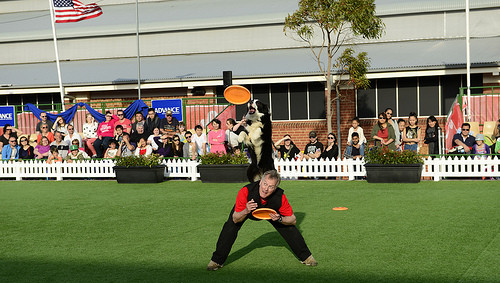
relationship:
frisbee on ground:
[327, 201, 356, 214] [6, 178, 499, 278]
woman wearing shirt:
[31, 136, 54, 159] [37, 140, 49, 153]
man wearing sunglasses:
[450, 123, 476, 159] [463, 125, 471, 133]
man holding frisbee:
[208, 167, 317, 267] [244, 202, 281, 223]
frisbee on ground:
[332, 206, 349, 210] [6, 178, 499, 278]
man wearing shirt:
[205, 169, 321, 272] [231, 179, 285, 217]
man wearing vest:
[205, 169, 321, 272] [244, 186, 284, 221]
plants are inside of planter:
[114, 156, 171, 184] [105, 158, 165, 181]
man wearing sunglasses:
[456, 118, 475, 152] [459, 122, 471, 138]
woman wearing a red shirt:
[371, 107, 399, 151] [377, 127, 387, 140]